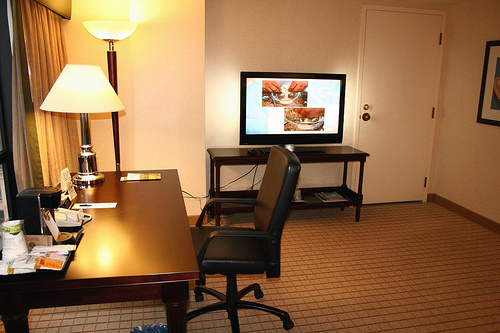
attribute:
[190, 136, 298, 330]
office chair — black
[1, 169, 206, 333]
table — wood, cherry wood, brown, long, wooden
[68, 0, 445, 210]
wall — recessed, white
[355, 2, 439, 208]
door — metal, white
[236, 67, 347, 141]
tv — large, flat screen, on, playing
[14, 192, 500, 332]
floor — carpeted, brown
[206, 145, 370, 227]
table — black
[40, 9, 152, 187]
lamps — lit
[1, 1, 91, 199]
curtains — brown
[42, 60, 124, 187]
lamp — on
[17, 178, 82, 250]
coffee maker — black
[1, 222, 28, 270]
cups — white